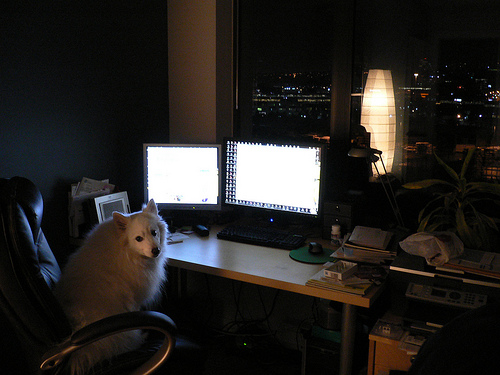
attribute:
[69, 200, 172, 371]
dog — white, sitting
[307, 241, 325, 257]
mouse — black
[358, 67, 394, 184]
light — reflection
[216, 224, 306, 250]
keyboard — black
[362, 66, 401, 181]
lamp — reflection